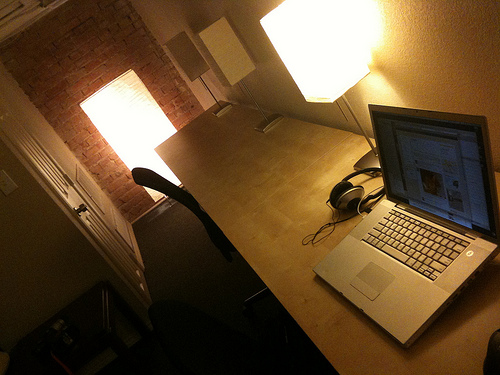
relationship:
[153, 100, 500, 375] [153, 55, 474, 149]
desk against wall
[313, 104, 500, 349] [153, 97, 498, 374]
computer on table surface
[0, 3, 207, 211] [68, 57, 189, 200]
wall with panel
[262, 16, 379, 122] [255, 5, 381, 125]
lamps with shade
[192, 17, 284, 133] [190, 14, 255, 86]
lamp with shade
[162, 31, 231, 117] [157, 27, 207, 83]
lamp with shade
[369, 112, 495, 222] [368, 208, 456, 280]
screen over keyboards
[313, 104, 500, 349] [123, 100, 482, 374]
computer on table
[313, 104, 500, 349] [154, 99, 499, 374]
computer on table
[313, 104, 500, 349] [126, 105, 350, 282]
computer on table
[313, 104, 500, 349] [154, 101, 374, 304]
computer on table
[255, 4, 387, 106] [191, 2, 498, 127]
lights on wall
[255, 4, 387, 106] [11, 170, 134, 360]
lights on wall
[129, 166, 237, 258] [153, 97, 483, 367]
chair under desk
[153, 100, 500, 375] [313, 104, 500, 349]
desk with computer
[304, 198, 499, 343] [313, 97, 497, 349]
keyboard on computer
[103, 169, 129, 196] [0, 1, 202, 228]
brick on wall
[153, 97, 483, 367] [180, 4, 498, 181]
desk against wall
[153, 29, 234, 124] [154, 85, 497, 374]
lamp in desk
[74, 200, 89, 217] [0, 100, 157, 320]
door knob in door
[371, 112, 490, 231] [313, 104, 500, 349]
screen in computer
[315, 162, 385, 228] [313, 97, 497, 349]
headphones next to computer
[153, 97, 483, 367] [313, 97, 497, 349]
desk on computer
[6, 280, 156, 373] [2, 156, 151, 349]
end table against wall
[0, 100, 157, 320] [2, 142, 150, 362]
door opened against wall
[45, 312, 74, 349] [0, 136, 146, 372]
container sitting against wall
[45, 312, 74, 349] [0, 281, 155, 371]
container sitting in area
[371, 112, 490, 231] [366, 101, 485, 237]
screen built into monitor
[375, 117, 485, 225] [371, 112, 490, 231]
information shown on screen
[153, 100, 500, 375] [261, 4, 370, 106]
desk with lamp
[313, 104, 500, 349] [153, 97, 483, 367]
computer on desk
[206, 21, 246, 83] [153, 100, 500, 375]
lamp on desk